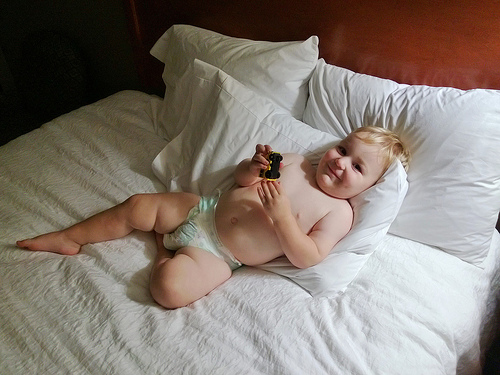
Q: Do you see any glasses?
A: No, there are no glasses.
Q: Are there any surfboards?
A: No, there are no surfboards.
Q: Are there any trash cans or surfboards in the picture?
A: No, there are no surfboards or trash cans.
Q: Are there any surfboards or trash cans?
A: No, there are no surfboards or trash cans.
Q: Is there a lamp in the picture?
A: No, there are no lamps.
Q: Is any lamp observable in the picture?
A: No, there are no lamps.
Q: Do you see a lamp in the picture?
A: No, there are no lamps.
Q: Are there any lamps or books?
A: No, there are no lamps or books.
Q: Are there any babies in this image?
A: Yes, there is a baby.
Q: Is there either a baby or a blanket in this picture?
A: Yes, there is a baby.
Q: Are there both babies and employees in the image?
A: No, there is a baby but no employees.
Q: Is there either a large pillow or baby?
A: Yes, there is a large baby.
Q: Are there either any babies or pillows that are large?
A: Yes, the baby is large.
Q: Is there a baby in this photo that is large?
A: Yes, there is a large baby.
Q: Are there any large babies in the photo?
A: Yes, there is a large baby.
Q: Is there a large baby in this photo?
A: Yes, there is a large baby.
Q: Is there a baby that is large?
A: Yes, there is a baby that is large.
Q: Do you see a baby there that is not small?
A: Yes, there is a large baby.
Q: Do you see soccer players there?
A: No, there are no soccer players.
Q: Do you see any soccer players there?
A: No, there are no soccer players.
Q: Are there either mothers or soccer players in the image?
A: No, there are no soccer players or mothers.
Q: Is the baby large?
A: Yes, the baby is large.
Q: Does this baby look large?
A: Yes, the baby is large.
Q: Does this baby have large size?
A: Yes, the baby is large.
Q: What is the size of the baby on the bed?
A: The baby is large.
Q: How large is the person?
A: The baby is large.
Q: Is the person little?
A: No, the baby is large.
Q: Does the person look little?
A: No, the baby is large.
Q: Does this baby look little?
A: No, the baby is large.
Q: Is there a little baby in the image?
A: No, there is a baby but he is large.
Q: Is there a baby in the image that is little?
A: No, there is a baby but he is large.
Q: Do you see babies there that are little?
A: No, there is a baby but he is large.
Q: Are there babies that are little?
A: No, there is a baby but he is large.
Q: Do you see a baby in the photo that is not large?
A: No, there is a baby but he is large.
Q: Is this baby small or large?
A: The baby is large.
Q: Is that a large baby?
A: Yes, that is a large baby.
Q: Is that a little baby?
A: No, that is a large baby.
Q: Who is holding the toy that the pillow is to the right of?
A: The baby is holding the toy.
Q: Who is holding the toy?
A: The baby is holding the toy.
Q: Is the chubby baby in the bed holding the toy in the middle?
A: Yes, the baby is holding the toy.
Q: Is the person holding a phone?
A: No, the baby is holding the toy.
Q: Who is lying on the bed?
A: The baby is lying on the bed.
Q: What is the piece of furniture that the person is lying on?
A: The piece of furniture is a bed.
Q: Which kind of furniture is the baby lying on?
A: The baby is lying on the bed.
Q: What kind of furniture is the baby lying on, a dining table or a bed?
A: The baby is lying on a bed.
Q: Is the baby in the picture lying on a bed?
A: Yes, the baby is lying on a bed.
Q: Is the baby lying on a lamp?
A: No, the baby is lying on a bed.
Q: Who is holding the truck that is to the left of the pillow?
A: The baby is holding the truck.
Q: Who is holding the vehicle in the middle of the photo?
A: The baby is holding the truck.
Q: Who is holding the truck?
A: The baby is holding the truck.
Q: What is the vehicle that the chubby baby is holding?
A: The vehicle is a truck.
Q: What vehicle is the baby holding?
A: The baby is holding the truck.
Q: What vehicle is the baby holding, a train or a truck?
A: The baby is holding a truck.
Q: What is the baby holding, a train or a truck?
A: The baby is holding a truck.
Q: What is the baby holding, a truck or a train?
A: The baby is holding a truck.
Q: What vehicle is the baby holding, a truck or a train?
A: The baby is holding a truck.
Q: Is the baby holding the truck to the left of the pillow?
A: Yes, the baby is holding the truck.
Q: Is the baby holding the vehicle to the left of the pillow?
A: Yes, the baby is holding the truck.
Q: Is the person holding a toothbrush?
A: No, the baby is holding the truck.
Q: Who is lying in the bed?
A: The baby is lying in the bed.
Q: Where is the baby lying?
A: The baby is lying in the bed.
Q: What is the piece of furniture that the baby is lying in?
A: The piece of furniture is a bed.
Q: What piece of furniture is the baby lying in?
A: The baby is lying in the bed.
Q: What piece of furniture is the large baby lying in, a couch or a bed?
A: The baby is lying in a bed.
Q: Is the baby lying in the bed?
A: Yes, the baby is lying in the bed.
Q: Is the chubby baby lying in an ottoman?
A: No, the baby is lying in the bed.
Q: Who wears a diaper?
A: The baby wears a diaper.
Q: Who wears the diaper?
A: The baby wears a diaper.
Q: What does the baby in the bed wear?
A: The baby wears a diaper.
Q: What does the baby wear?
A: The baby wears a diaper.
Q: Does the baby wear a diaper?
A: Yes, the baby wears a diaper.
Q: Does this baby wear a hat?
A: No, the baby wears a diaper.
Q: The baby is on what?
A: The baby is on the bed.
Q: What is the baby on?
A: The baby is on the bed.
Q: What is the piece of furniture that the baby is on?
A: The piece of furniture is a bed.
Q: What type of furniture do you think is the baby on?
A: The baby is on the bed.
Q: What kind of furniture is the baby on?
A: The baby is on the bed.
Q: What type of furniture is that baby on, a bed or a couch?
A: The baby is on a bed.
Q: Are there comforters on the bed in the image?
A: No, there is a baby on the bed.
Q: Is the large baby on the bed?
A: Yes, the baby is on the bed.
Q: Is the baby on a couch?
A: No, the baby is on the bed.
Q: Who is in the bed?
A: The baby is in the bed.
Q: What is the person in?
A: The baby is in the bed.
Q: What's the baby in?
A: The baby is in the bed.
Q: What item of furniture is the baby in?
A: The baby is in the bed.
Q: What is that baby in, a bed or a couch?
A: The baby is in a bed.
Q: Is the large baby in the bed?
A: Yes, the baby is in the bed.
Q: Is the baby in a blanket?
A: No, the baby is in the bed.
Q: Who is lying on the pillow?
A: The baby is lying on the pillow.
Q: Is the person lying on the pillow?
A: Yes, the baby is lying on the pillow.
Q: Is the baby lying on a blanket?
A: No, the baby is lying on the pillow.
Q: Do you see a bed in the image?
A: Yes, there is a bed.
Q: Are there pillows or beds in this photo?
A: Yes, there is a bed.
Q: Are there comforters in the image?
A: No, there are no comforters.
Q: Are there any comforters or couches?
A: No, there are no comforters or couches.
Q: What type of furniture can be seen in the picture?
A: The furniture is a bed.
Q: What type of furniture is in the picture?
A: The furniture is a bed.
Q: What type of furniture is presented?
A: The furniture is a bed.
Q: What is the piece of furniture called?
A: The piece of furniture is a bed.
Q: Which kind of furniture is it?
A: The piece of furniture is a bed.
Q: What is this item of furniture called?
A: This is a bed.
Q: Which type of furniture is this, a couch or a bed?
A: This is a bed.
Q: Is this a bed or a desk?
A: This is a bed.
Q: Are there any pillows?
A: Yes, there is a pillow.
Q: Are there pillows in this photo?
A: Yes, there is a pillow.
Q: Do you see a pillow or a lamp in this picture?
A: Yes, there is a pillow.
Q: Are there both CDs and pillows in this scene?
A: No, there is a pillow but no cds.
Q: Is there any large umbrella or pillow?
A: Yes, there is a large pillow.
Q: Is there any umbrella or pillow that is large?
A: Yes, the pillow is large.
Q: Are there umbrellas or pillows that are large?
A: Yes, the pillow is large.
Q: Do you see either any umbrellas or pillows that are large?
A: Yes, the pillow is large.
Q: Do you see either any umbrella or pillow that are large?
A: Yes, the pillow is large.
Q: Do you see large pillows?
A: Yes, there is a large pillow.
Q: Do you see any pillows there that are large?
A: Yes, there is a large pillow.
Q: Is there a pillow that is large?
A: Yes, there is a pillow that is large.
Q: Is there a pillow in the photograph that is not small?
A: Yes, there is a large pillow.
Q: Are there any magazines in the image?
A: No, there are no magazines.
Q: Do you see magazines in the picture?
A: No, there are no magazines.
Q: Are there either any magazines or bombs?
A: No, there are no magazines or bombs.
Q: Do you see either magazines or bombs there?
A: No, there are no magazines or bombs.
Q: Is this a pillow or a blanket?
A: This is a pillow.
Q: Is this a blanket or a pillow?
A: This is a pillow.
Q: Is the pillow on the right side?
A: Yes, the pillow is on the right of the image.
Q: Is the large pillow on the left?
A: No, the pillow is on the right of the image.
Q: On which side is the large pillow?
A: The pillow is on the right of the image.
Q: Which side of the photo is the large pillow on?
A: The pillow is on the right of the image.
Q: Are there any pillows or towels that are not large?
A: No, there is a pillow but it is large.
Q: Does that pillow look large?
A: Yes, the pillow is large.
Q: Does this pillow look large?
A: Yes, the pillow is large.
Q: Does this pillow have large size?
A: Yes, the pillow is large.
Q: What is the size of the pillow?
A: The pillow is large.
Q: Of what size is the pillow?
A: The pillow is large.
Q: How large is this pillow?
A: The pillow is large.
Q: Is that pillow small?
A: No, the pillow is large.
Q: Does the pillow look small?
A: No, the pillow is large.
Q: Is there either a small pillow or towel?
A: No, there is a pillow but it is large.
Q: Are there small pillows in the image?
A: No, there is a pillow but it is large.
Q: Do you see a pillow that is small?
A: No, there is a pillow but it is large.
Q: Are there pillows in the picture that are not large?
A: No, there is a pillow but it is large.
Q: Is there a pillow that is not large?
A: No, there is a pillow but it is large.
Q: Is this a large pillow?
A: Yes, this is a large pillow.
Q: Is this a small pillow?
A: No, this is a large pillow.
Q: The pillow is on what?
A: The pillow is on the bed.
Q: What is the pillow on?
A: The pillow is on the bed.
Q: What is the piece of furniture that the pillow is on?
A: The piece of furniture is a bed.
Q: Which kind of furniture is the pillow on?
A: The pillow is on the bed.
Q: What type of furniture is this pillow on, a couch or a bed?
A: The pillow is on a bed.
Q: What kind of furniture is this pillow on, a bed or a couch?
A: The pillow is on a bed.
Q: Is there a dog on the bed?
A: No, there is a pillow on the bed.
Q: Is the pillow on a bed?
A: Yes, the pillow is on a bed.